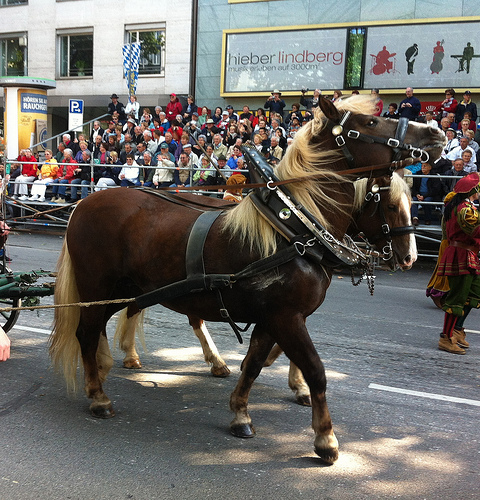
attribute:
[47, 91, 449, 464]
horse — brown, trotting, walking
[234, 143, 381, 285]
bridle — black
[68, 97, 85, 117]
parking sign — blue, white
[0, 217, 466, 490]
asphalt — gray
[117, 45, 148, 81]
flag — blue, white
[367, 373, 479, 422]
line — white